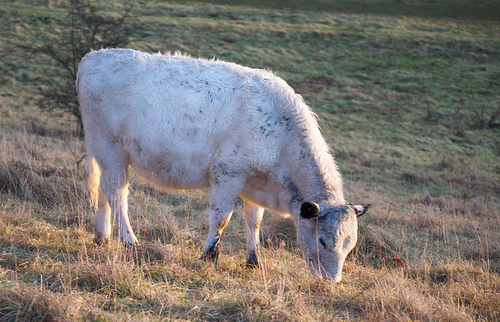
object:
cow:
[76, 47, 370, 283]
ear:
[299, 200, 322, 219]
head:
[296, 199, 374, 285]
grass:
[1, 0, 500, 319]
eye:
[318, 236, 329, 250]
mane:
[267, 75, 343, 201]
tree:
[16, 1, 158, 139]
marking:
[199, 237, 221, 265]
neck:
[269, 125, 346, 208]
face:
[315, 234, 360, 284]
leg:
[200, 165, 247, 264]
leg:
[241, 197, 264, 271]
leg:
[89, 149, 142, 249]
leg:
[93, 189, 112, 246]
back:
[81, 47, 278, 79]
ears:
[350, 200, 372, 219]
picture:
[1, 1, 499, 322]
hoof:
[125, 242, 142, 250]